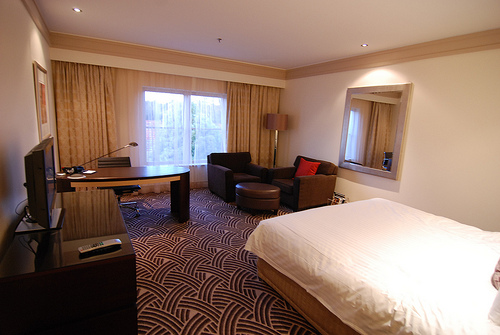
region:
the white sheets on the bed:
[332, 221, 417, 280]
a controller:
[81, 237, 121, 254]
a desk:
[136, 162, 173, 176]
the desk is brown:
[113, 166, 133, 180]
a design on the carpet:
[178, 259, 228, 289]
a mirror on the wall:
[347, 109, 389, 165]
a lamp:
[258, 110, 289, 165]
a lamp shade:
[266, 113, 290, 130]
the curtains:
[63, 81, 103, 135]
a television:
[41, 147, 64, 204]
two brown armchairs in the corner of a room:
[208, 150, 338, 210]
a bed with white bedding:
[245, 195, 499, 333]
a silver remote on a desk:
[76, 235, 122, 254]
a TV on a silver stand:
[17, 135, 64, 232]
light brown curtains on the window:
[52, 62, 282, 171]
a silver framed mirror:
[337, 81, 412, 181]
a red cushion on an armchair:
[293, 158, 318, 180]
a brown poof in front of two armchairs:
[234, 183, 280, 215]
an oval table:
[56, 165, 192, 218]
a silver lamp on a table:
[64, 140, 138, 175]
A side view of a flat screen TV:
[15, 128, 71, 240]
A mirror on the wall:
[329, 77, 429, 186]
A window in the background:
[134, 79, 236, 171]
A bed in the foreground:
[238, 174, 498, 334]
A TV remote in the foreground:
[71, 228, 128, 266]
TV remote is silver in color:
[73, 228, 125, 270]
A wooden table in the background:
[48, 129, 204, 242]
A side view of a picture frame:
[28, 54, 63, 146]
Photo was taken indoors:
[1, 5, 497, 330]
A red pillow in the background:
[289, 152, 324, 191]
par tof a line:
[296, 213, 316, 253]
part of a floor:
[213, 271, 243, 303]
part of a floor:
[203, 196, 240, 253]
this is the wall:
[423, 69, 485, 209]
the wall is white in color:
[431, 78, 470, 143]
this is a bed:
[326, 203, 461, 319]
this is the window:
[143, 87, 219, 158]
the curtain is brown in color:
[60, 78, 91, 109]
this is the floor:
[143, 227, 203, 295]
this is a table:
[130, 157, 180, 187]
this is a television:
[32, 132, 73, 205]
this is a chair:
[248, 143, 300, 183]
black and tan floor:
[150, 236, 268, 325]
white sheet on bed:
[282, 179, 494, 326]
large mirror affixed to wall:
[334, 81, 415, 183]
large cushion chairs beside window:
[201, 150, 339, 211]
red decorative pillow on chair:
[290, 154, 323, 179]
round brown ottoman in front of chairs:
[230, 180, 282, 214]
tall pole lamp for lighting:
[264, 107, 289, 168]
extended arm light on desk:
[70, 138, 139, 169]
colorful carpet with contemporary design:
[118, 189, 331, 334]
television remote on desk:
[73, 233, 125, 258]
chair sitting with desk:
[91, 153, 143, 218]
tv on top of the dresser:
[20, 135, 57, 227]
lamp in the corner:
[262, 111, 292, 171]